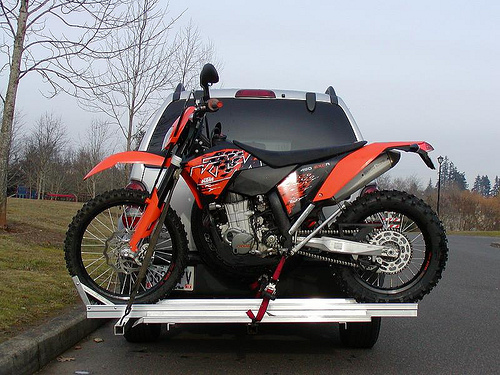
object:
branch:
[131, 55, 169, 91]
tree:
[80, 8, 190, 156]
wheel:
[62, 188, 190, 307]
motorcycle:
[63, 62, 448, 305]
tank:
[267, 149, 402, 241]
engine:
[191, 173, 325, 271]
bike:
[64, 62, 449, 307]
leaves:
[142, 28, 179, 57]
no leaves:
[145, 24, 202, 78]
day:
[315, 23, 410, 79]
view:
[49, 21, 178, 172]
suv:
[114, 83, 386, 350]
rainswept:
[448, 245, 481, 308]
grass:
[15, 244, 53, 317]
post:
[433, 154, 469, 213]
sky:
[267, 21, 317, 55]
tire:
[63, 188, 188, 306]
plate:
[144, 264, 195, 290]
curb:
[38, 315, 76, 351]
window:
[142, 98, 358, 171]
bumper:
[174, 265, 354, 318]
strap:
[246, 255, 289, 337]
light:
[235, 88, 276, 99]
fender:
[82, 151, 169, 180]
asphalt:
[461, 250, 487, 292]